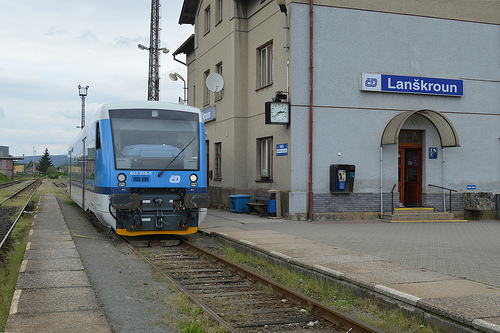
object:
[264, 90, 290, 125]
clock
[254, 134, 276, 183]
window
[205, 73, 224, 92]
satellite dish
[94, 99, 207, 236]
train front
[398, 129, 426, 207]
door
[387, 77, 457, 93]
writing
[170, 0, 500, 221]
building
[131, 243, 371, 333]
track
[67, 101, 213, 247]
train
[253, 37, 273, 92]
window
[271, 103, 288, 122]
face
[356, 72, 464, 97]
sign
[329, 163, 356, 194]
payphone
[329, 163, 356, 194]
metal protector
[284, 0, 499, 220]
wall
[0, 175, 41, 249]
track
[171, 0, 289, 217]
wall